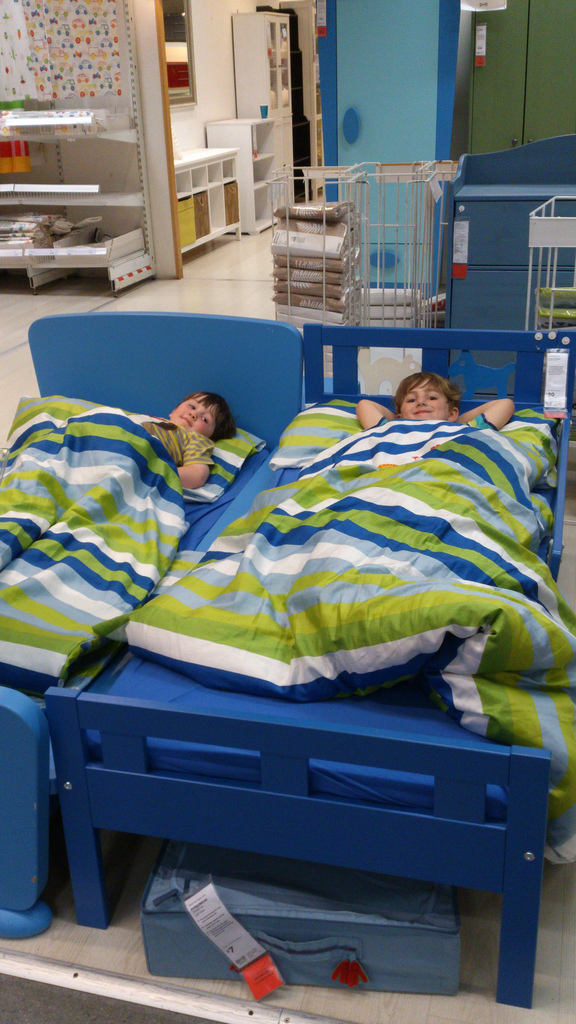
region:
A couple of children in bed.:
[2, 360, 572, 1019]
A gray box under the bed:
[143, 857, 466, 996]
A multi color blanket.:
[129, 428, 574, 724]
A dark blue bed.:
[55, 319, 575, 1009]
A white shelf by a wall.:
[7, 96, 157, 304]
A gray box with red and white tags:
[141, 860, 475, 1005]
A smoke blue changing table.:
[442, 136, 575, 390]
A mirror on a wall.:
[155, 2, 197, 113]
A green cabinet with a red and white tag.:
[465, 1, 571, 149]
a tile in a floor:
[236, 233, 258, 247]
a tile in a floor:
[239, 224, 255, 242]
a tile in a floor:
[92, 915, 150, 985]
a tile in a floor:
[312, 979, 370, 1021]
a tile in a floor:
[372, 987, 422, 1019]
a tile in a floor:
[414, 984, 473, 1021]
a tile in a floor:
[498, 961, 565, 1013]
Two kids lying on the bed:
[9, 306, 574, 1007]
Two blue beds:
[7, 308, 573, 1014]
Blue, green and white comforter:
[90, 416, 573, 874]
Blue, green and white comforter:
[0, 400, 192, 696]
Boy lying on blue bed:
[0, 306, 306, 946]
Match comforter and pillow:
[91, 394, 574, 877]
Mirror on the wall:
[162, 0, 203, 111]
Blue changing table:
[439, 131, 574, 414]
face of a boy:
[390, 368, 463, 423]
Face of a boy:
[166, 388, 235, 439]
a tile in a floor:
[2, 288, 20, 311]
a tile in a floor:
[24, 910, 82, 959]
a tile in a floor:
[73, 920, 147, 975]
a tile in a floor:
[103, 878, 155, 932]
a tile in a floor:
[173, 962, 250, 999]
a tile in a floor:
[242, 976, 305, 1003]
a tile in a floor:
[292, 978, 391, 1017]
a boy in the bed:
[357, 361, 473, 473]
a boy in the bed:
[118, 385, 206, 473]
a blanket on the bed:
[52, 385, 221, 589]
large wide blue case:
[142, 829, 467, 1004]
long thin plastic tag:
[180, 872, 286, 1004]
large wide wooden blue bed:
[46, 322, 570, 1012]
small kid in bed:
[355, 374, 514, 429]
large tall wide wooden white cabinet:
[233, 11, 298, 238]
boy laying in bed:
[127, 390, 238, 491]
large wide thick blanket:
[0, 395, 266, 701]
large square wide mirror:
[165, 24, 199, 105]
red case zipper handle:
[330, 960, 369, 992]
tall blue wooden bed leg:
[495, 746, 555, 1009]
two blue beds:
[0, 309, 573, 1010]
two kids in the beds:
[109, 354, 521, 487]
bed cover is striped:
[152, 421, 573, 717]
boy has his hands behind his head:
[352, 366, 526, 439]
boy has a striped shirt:
[130, 410, 218, 471]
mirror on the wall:
[157, 1, 203, 100]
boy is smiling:
[384, 374, 461, 422]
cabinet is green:
[463, 2, 574, 162]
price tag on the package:
[185, 880, 286, 1001]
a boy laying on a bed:
[343, 367, 520, 485]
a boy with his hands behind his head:
[350, 368, 519, 451]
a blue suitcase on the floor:
[119, 887, 475, 975]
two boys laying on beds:
[76, 308, 520, 495]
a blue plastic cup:
[255, 96, 269, 122]